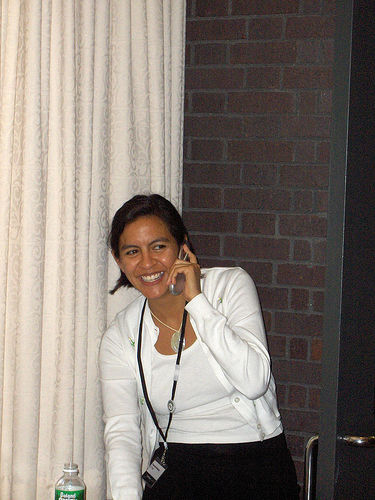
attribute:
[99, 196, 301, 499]
girl — smiling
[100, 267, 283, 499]
cardigan — white, lightweight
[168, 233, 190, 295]
phone — silver, gray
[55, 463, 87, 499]
water bottle — uncapped, open, plastic, capless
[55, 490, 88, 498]
label — green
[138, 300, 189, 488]
lanyard — black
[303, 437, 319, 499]
handle — gray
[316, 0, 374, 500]
door — tall, gray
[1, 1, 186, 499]
curtain — white, long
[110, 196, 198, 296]
hair — black, short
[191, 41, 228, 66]
brick — red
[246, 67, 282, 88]
brick — red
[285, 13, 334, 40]
brick — red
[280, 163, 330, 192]
brick — red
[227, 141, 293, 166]
brick — red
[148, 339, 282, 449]
undershirt — white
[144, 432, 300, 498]
bottoms — black